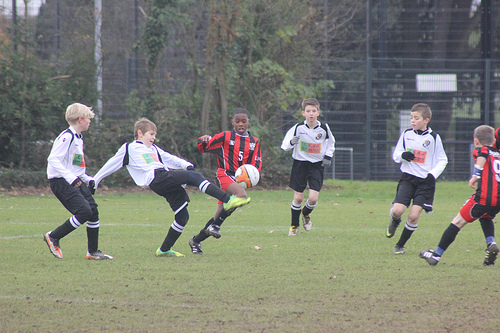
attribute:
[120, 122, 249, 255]
kid — running, playing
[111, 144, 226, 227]
uniform — white, black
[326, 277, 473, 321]
grass — brown, worn, green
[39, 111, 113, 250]
kid — playing, stealing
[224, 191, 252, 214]
shoe — green, yellow, white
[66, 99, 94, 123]
hair — blonde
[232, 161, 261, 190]
soccer ball — orange, white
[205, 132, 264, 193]
uniform — black, red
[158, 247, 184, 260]
shoe — yellow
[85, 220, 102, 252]
sock — knee length, black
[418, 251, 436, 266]
shoe — black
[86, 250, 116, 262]
shoe — orange, white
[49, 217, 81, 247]
sock — black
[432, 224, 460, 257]
sock — blue, black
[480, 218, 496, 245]
sock — blue, black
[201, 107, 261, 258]
kid — playing, young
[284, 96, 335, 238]
kid — playing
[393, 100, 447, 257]
kid — playing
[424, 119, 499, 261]
kid — playing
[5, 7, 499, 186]
fence — tall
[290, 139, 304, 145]
glove — gray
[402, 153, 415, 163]
glove — black